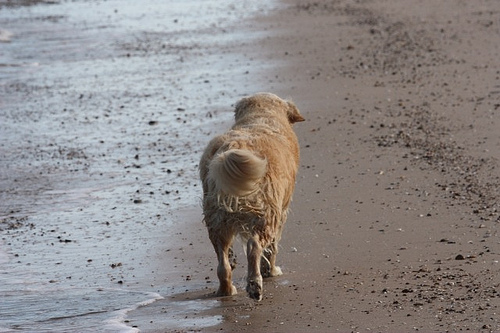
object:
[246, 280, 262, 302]
paw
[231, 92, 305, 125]
head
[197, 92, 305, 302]
dog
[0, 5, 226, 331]
ocean water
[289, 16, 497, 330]
sand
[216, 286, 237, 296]
paw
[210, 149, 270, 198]
tail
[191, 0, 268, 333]
line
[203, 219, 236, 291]
leg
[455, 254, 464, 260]
rock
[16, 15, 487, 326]
beach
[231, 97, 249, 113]
ear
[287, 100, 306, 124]
ear